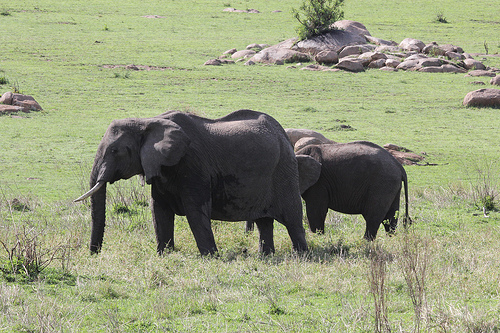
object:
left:
[2, 0, 82, 332]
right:
[446, 0, 499, 326]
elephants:
[74, 108, 313, 261]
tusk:
[73, 182, 102, 202]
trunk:
[89, 171, 107, 255]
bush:
[0, 179, 82, 282]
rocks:
[203, 20, 499, 108]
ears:
[139, 117, 191, 185]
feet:
[156, 243, 173, 258]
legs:
[180, 187, 219, 260]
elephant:
[295, 141, 413, 242]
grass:
[0, 0, 499, 333]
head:
[87, 118, 191, 185]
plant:
[290, 0, 345, 41]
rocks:
[0, 91, 43, 118]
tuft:
[455, 147, 499, 217]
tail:
[402, 167, 413, 229]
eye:
[111, 149, 115, 153]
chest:
[151, 161, 184, 216]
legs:
[283, 197, 308, 253]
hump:
[156, 109, 197, 126]